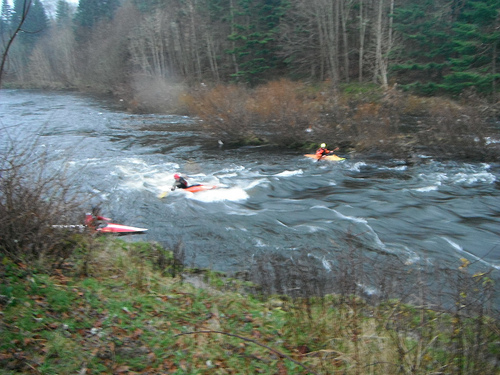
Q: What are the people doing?
A: Kayaking.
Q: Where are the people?
A: On the river.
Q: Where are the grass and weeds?
A: By river bank.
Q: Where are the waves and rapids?
A: In river.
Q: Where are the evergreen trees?
A: In woods.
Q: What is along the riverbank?
A: Bare trees, evergreens and shrubs.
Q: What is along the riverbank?
A: Bare shrubs, weeds and reeds.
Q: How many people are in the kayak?
A: Three.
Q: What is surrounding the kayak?
A: White water.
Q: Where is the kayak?
A: River.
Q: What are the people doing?
A: Kayaking.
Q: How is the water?
A: Rough.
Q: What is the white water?
A: Waves.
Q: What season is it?
A: Fall.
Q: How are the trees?
A: Bare.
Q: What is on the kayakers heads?
A: Helmets.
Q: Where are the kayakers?
A: Rivers.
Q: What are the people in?
A: Kayaks.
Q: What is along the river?
A: Vegetation.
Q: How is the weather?
A: Overcast.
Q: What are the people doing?
A: Kayaking.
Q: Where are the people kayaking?
A: In a river.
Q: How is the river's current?
A: Fast.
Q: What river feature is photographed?
A: Rapids.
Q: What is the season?
A: Fall.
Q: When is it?
A: Day time.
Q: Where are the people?
A: In the river.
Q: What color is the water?
A: Blue and white.